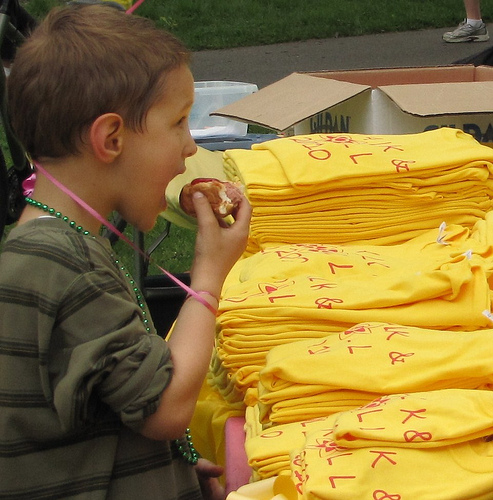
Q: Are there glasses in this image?
A: No, there are no glasses.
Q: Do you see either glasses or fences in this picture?
A: No, there are no glasses or fences.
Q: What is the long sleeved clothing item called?
A: The clothing item is a shirt.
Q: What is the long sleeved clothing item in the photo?
A: The clothing item is a shirt.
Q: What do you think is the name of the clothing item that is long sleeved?
A: The clothing item is a shirt.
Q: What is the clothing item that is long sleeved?
A: The clothing item is a shirt.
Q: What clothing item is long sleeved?
A: The clothing item is a shirt.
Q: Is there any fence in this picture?
A: No, there are no fences.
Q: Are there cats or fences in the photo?
A: No, there are no fences or cats.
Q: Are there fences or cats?
A: No, there are no fences or cats.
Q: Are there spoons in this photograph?
A: No, there are no spoons.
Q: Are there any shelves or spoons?
A: No, there are no spoons or shelves.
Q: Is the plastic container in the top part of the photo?
A: Yes, the container is in the top of the image.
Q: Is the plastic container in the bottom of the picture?
A: No, the container is in the top of the image.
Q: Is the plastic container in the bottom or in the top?
A: The container is in the top of the image.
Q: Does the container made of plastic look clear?
A: Yes, the container is clear.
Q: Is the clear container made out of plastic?
A: Yes, the container is made of plastic.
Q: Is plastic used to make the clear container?
A: Yes, the container is made of plastic.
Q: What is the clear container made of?
A: The container is made of plastic.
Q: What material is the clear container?
A: The container is made of plastic.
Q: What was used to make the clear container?
A: The container is made of plastic.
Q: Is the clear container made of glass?
A: No, the container is made of plastic.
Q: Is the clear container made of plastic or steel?
A: The container is made of plastic.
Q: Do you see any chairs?
A: No, there are no chairs.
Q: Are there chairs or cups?
A: No, there are no chairs or cups.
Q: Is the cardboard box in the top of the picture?
A: Yes, the box is in the top of the image.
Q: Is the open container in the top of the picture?
A: Yes, the box is in the top of the image.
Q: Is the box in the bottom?
A: No, the box is in the top of the image.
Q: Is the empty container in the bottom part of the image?
A: No, the box is in the top of the image.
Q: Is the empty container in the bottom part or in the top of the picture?
A: The box is in the top of the image.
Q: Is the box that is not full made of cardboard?
A: Yes, the box is made of cardboard.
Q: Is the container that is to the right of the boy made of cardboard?
A: Yes, the box is made of cardboard.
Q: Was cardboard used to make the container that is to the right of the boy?
A: Yes, the box is made of cardboard.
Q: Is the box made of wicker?
A: No, the box is made of cardboard.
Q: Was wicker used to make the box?
A: No, the box is made of cardboard.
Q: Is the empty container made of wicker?
A: No, the box is made of cardboard.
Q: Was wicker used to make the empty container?
A: No, the box is made of cardboard.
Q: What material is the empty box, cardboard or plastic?
A: The box is made of cardboard.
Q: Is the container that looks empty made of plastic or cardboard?
A: The box is made of cardboard.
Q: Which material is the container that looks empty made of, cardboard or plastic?
A: The box is made of cardboard.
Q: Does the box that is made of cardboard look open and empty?
A: Yes, the box is open and empty.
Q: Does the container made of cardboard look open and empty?
A: Yes, the box is open and empty.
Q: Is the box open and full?
A: No, the box is open but empty.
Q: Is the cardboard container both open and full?
A: No, the box is open but empty.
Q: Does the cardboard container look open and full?
A: No, the box is open but empty.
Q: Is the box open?
A: Yes, the box is open.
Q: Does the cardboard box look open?
A: Yes, the box is open.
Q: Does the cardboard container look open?
A: Yes, the box is open.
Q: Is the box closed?
A: No, the box is open.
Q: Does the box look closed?
A: No, the box is open.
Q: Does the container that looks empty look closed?
A: No, the box is open.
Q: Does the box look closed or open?
A: The box is open.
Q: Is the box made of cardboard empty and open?
A: Yes, the box is empty and open.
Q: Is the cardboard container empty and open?
A: Yes, the box is empty and open.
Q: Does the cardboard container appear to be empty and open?
A: Yes, the box is empty and open.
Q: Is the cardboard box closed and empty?
A: No, the box is empty but open.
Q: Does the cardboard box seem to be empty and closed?
A: No, the box is empty but open.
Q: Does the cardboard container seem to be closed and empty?
A: No, the box is empty but open.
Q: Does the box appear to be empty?
A: Yes, the box is empty.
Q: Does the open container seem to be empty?
A: Yes, the box is empty.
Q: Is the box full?
A: No, the box is empty.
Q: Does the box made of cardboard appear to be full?
A: No, the box is empty.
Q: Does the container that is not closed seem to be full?
A: No, the box is empty.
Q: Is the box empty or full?
A: The box is empty.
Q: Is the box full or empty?
A: The box is empty.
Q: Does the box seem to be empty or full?
A: The box is empty.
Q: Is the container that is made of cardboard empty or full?
A: The box is empty.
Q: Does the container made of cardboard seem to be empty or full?
A: The box is empty.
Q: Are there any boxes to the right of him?
A: Yes, there is a box to the right of the boy.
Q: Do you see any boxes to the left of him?
A: No, the box is to the right of the boy.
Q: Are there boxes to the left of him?
A: No, the box is to the right of the boy.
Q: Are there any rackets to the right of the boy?
A: No, there is a box to the right of the boy.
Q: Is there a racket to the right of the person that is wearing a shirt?
A: No, there is a box to the right of the boy.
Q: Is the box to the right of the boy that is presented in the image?
A: Yes, the box is to the right of the boy.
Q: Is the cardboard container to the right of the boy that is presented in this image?
A: Yes, the box is to the right of the boy.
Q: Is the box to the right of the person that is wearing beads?
A: Yes, the box is to the right of the boy.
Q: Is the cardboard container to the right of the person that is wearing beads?
A: Yes, the box is to the right of the boy.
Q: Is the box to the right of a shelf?
A: No, the box is to the right of the boy.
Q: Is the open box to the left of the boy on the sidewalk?
A: No, the box is to the right of the boy.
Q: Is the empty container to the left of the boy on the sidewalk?
A: No, the box is to the right of the boy.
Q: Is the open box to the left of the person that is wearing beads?
A: No, the box is to the right of the boy.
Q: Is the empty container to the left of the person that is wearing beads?
A: No, the box is to the right of the boy.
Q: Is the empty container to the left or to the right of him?
A: The box is to the right of the boy.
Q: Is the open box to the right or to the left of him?
A: The box is to the right of the boy.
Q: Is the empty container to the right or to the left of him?
A: The box is to the right of the boy.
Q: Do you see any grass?
A: Yes, there is grass.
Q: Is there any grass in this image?
A: Yes, there is grass.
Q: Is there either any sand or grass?
A: Yes, there is grass.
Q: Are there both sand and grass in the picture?
A: No, there is grass but no sand.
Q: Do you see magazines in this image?
A: No, there are no magazines.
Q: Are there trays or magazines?
A: No, there are no magazines or trays.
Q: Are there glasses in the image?
A: No, there are no glasses.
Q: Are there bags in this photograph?
A: No, there are no bags.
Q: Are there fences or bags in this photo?
A: No, there are no bags or fences.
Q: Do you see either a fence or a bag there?
A: No, there are no bags or fences.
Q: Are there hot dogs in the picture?
A: Yes, there is a hot dog.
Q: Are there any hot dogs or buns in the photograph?
A: Yes, there is a hot dog.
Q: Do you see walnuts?
A: No, there are no walnuts.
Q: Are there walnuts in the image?
A: No, there are no walnuts.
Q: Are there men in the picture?
A: No, there are no men.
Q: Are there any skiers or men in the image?
A: No, there are no men or skiers.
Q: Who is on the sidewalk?
A: The boy is on the sidewalk.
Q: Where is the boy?
A: The boy is on the side walk.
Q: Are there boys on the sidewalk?
A: Yes, there is a boy on the sidewalk.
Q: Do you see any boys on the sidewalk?
A: Yes, there is a boy on the sidewalk.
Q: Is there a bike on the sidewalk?
A: No, there is a boy on the sidewalk.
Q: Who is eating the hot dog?
A: The boy is eating the hot dog.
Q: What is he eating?
A: The boy is eating a hot dog.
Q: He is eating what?
A: The boy is eating a hot dog.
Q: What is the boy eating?
A: The boy is eating a hot dog.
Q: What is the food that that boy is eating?
A: The food is a hot dog.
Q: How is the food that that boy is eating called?
A: The food is a hot dog.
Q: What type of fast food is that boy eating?
A: The boy is eating a hot dog.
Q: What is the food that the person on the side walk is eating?
A: The food is a hot dog.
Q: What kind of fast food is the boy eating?
A: The boy is eating a hot dog.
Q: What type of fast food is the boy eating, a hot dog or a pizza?
A: The boy is eating a hot dog.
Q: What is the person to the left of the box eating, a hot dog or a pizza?
A: The boy is eating a hot dog.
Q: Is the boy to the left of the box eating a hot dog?
A: Yes, the boy is eating a hot dog.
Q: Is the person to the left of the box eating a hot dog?
A: Yes, the boy is eating a hot dog.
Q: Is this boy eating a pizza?
A: No, the boy is eating a hot dog.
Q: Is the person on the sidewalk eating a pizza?
A: No, the boy is eating a hot dog.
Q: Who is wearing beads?
A: The boy is wearing beads.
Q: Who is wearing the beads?
A: The boy is wearing beads.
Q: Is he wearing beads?
A: Yes, the boy is wearing beads.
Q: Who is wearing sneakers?
A: The boy is wearing sneakers.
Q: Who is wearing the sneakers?
A: The boy is wearing sneakers.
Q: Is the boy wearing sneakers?
A: Yes, the boy is wearing sneakers.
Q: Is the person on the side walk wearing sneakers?
A: Yes, the boy is wearing sneakers.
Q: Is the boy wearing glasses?
A: No, the boy is wearing sneakers.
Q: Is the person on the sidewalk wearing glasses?
A: No, the boy is wearing sneakers.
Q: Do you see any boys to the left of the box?
A: Yes, there is a boy to the left of the box.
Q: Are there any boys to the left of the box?
A: Yes, there is a boy to the left of the box.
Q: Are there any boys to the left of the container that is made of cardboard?
A: Yes, there is a boy to the left of the box.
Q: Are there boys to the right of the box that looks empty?
A: No, the boy is to the left of the box.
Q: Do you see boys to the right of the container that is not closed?
A: No, the boy is to the left of the box.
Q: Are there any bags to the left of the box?
A: No, there is a boy to the left of the box.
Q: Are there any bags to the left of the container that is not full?
A: No, there is a boy to the left of the box.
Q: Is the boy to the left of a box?
A: Yes, the boy is to the left of a box.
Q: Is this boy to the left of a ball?
A: No, the boy is to the left of a box.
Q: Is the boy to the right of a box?
A: No, the boy is to the left of a box.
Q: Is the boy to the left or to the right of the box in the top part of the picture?
A: The boy is to the left of the box.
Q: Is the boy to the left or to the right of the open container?
A: The boy is to the left of the box.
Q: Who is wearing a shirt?
A: The boy is wearing a shirt.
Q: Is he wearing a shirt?
A: Yes, the boy is wearing a shirt.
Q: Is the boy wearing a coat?
A: No, the boy is wearing a shirt.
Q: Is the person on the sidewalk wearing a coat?
A: No, the boy is wearing a shirt.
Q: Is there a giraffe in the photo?
A: No, there are no giraffes.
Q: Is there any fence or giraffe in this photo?
A: No, there are no giraffes or fences.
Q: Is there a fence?
A: No, there are no fences.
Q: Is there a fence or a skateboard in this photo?
A: No, there are no fences or skateboards.